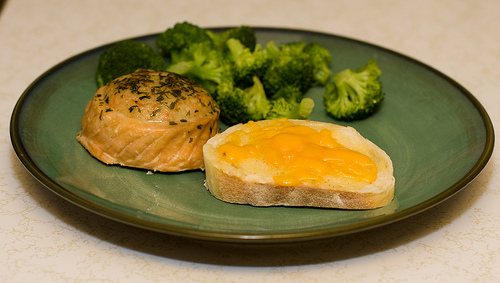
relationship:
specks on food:
[94, 71, 232, 126] [61, 53, 227, 189]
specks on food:
[94, 71, 232, 126] [64, 56, 241, 180]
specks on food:
[94, 43, 232, 126] [64, 56, 241, 180]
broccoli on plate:
[326, 62, 386, 118] [9, 22, 497, 247]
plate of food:
[9, 22, 497, 247] [54, 17, 417, 214]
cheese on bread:
[221, 117, 384, 191] [203, 118, 398, 210]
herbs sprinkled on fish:
[92, 69, 218, 147] [77, 66, 223, 173]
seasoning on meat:
[89, 66, 221, 130] [75, 65, 217, 172]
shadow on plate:
[77, 166, 137, 204] [9, 22, 497, 247]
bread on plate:
[203, 117, 398, 210] [9, 22, 497, 247]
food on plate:
[80, 67, 226, 175] [9, 22, 497, 247]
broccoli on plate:
[93, 20, 386, 122] [9, 22, 497, 247]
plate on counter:
[9, 22, 497, 247] [0, 0, 498, 278]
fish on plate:
[77, 66, 223, 174] [9, 22, 497, 247]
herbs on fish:
[92, 69, 218, 129] [73, 65, 218, 169]